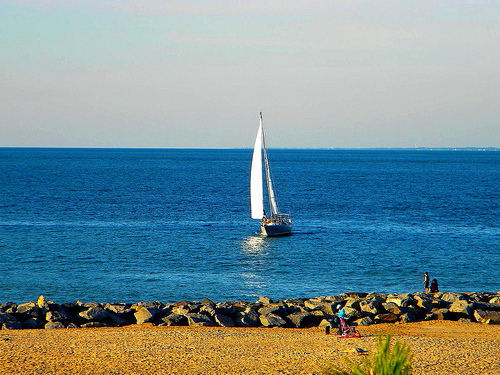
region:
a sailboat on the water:
[242, 118, 347, 261]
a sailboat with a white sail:
[211, 109, 346, 259]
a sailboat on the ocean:
[221, 133, 375, 253]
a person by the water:
[320, 283, 390, 344]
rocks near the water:
[119, 287, 349, 344]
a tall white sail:
[249, 114, 320, 228]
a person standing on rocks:
[415, 263, 460, 293]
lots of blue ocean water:
[49, 139, 221, 241]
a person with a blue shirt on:
[332, 291, 364, 331]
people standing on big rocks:
[384, 266, 459, 301]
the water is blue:
[86, 99, 467, 286]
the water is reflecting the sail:
[217, 206, 294, 270]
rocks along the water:
[3, 276, 479, 329]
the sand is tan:
[46, 314, 299, 369]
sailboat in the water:
[201, 78, 316, 278]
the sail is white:
[214, 83, 309, 245]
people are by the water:
[382, 245, 477, 312]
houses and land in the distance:
[377, 130, 492, 166]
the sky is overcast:
[75, 35, 450, 160]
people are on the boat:
[234, 177, 307, 250]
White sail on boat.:
[238, 142, 283, 237]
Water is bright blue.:
[80, 160, 210, 270]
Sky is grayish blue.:
[105, 38, 325, 88]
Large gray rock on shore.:
[138, 305, 153, 318]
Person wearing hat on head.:
[331, 299, 343, 315]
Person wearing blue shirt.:
[328, 305, 343, 323]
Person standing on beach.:
[334, 292, 378, 352]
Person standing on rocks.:
[417, 268, 432, 295]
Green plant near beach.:
[332, 348, 405, 373]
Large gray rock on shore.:
[371, 296, 395, 313]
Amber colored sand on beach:
[1, 327, 495, 374]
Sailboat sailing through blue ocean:
[228, 105, 311, 250]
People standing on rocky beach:
[417, 268, 444, 298]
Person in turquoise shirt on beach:
[319, 300, 370, 347]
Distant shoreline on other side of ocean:
[238, 141, 498, 154]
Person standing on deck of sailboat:
[258, 207, 269, 225]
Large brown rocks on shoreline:
[3, 288, 495, 326]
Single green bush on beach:
[325, 333, 424, 374]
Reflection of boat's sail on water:
[233, 226, 268, 288]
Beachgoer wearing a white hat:
[329, 302, 350, 334]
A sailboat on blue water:
[230, 107, 305, 258]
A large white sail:
[242, 100, 287, 215]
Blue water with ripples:
[102, 190, 207, 270]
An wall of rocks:
[16, 290, 311, 325]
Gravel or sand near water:
[130, 322, 295, 367]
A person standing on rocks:
[415, 266, 435, 291]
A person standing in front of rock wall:
[320, 295, 370, 355]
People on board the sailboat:
[263, 210, 291, 224]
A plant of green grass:
[315, 341, 410, 372]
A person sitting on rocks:
[426, 273, 441, 289]